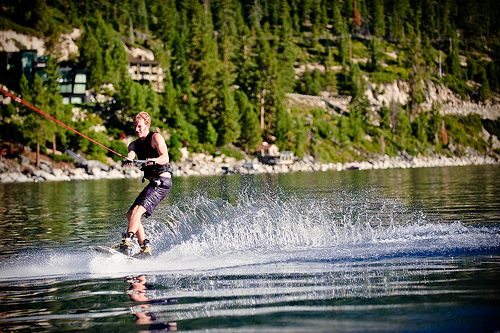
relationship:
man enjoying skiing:
[108, 111, 174, 253] [0, 88, 174, 264]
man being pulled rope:
[108, 111, 174, 253] [25, 99, 78, 141]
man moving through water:
[108, 111, 174, 253] [255, 190, 375, 287]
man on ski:
[108, 111, 174, 253] [97, 232, 139, 268]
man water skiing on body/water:
[108, 111, 174, 253] [0, 162, 499, 332]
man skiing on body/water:
[108, 111, 174, 253] [0, 162, 499, 332]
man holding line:
[125, 99, 192, 242] [23, 93, 106, 144]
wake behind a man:
[200, 209, 466, 263] [108, 111, 174, 253]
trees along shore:
[152, 8, 294, 157] [210, 156, 433, 171]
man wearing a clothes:
[108, 111, 174, 253] [127, 131, 173, 178]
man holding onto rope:
[108, 111, 174, 253] [3, 80, 126, 161]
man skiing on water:
[108, 111, 174, 253] [192, 172, 443, 329]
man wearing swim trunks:
[108, 111, 174, 253] [131, 171, 172, 217]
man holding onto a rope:
[108, 111, 174, 253] [0, 86, 131, 162]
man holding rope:
[108, 111, 174, 253] [3, 80, 126, 161]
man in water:
[108, 111, 174, 253] [0, 149, 495, 330]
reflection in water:
[104, 264, 177, 331] [0, 149, 495, 330]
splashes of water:
[120, 184, 495, 273] [0, 149, 495, 330]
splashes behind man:
[120, 184, 495, 273] [108, 111, 174, 253]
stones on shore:
[1, 151, 497, 185] [4, 137, 497, 192]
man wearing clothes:
[108, 111, 174, 253] [119, 131, 177, 217]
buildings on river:
[5, 40, 168, 126] [2, 154, 495, 328]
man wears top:
[108, 111, 174, 253] [117, 131, 176, 174]